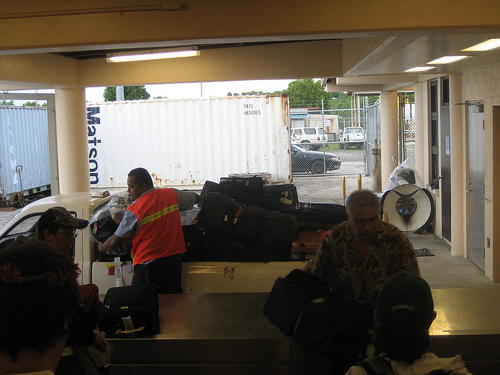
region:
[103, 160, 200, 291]
a man wearing an orange vest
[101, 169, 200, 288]
a man loading bags onto a truck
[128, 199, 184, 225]
yellow stripe on the man;s orange vest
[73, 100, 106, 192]
blue lettering on a white shipping container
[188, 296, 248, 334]
grey metal surface of the counter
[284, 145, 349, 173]
a black car parked on the street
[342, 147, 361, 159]
black asphalt of the street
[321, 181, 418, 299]
a man wearing a hawaiian shirt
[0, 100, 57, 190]
a blue shipping container on the ground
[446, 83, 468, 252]
white pillar of the building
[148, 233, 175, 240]
the vest is orange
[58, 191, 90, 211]
the truck is white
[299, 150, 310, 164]
the car is black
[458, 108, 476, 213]
the door is closed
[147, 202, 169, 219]
the stripe is yellow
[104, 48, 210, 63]
the light is on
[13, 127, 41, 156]
the shipping container is light blue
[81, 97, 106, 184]
the word is blue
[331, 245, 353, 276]
the shirt is green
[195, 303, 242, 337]
the counter is gray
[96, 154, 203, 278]
man wearing orange vest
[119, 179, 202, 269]
orange vest has yellow stripe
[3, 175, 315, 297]
person stand next to truck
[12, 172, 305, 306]
pick up truck is white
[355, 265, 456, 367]
person wearing baseball hat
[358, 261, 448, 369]
person has ponytail through hat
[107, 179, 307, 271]
luggage in back of truck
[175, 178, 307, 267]
luggage is black with straps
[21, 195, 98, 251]
person wearing hat with print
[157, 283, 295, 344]
counter top is metallic silver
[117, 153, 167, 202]
head of the man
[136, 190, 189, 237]
orange and yellow outfit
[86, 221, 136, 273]
arm of the man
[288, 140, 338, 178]
car behind a fence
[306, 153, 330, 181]
tire of the car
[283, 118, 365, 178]
cars in the background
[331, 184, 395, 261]
head of a person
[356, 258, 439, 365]
hat on the man's head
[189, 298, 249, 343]
table next to people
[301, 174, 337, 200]
ground in the photo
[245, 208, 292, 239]
luggage in the truck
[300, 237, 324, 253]
luggage in the truck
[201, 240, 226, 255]
luggage in the truck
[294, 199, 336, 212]
luggage in the truck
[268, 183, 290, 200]
luggage in the truck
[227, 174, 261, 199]
luggage in the truck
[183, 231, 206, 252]
luggage in the truck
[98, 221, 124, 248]
luggage in the truck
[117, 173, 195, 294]
worker in safety vest